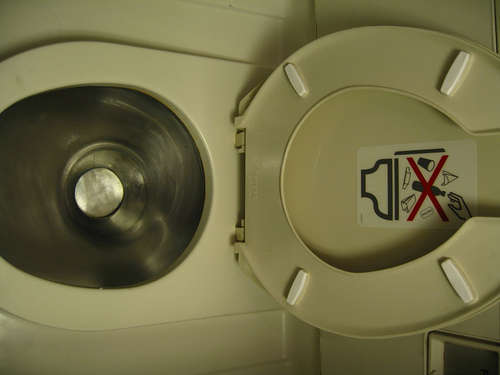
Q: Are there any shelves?
A: No, there are no shelves.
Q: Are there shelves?
A: No, there are no shelves.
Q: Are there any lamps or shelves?
A: No, there are no shelves or lamps.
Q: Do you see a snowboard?
A: No, there are no snowboards.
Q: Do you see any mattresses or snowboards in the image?
A: No, there are no snowboards or mattresses.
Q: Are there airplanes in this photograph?
A: Yes, there is an airplane.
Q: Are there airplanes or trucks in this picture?
A: Yes, there is an airplane.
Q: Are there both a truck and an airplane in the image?
A: No, there is an airplane but no trucks.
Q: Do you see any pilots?
A: No, there are no pilots.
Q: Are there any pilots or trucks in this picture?
A: No, there are no pilots or trucks.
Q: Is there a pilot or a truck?
A: No, there are no pilots or trucks.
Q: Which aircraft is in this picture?
A: The aircraft is an airplane.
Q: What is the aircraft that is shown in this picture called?
A: The aircraft is an airplane.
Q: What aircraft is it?
A: The aircraft is an airplane.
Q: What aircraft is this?
A: This is an airplane.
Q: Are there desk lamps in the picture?
A: No, there are no desk lamps.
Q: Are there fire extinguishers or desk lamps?
A: No, there are no desk lamps or fire extinguishers.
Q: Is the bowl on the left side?
A: Yes, the bowl is on the left of the image.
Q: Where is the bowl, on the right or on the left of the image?
A: The bowl is on the left of the image.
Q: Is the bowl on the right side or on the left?
A: The bowl is on the left of the image.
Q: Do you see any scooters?
A: No, there are no scooters.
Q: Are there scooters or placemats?
A: No, there are no scooters or placemats.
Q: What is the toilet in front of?
A: The toilet is in front of the wall.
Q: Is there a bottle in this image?
A: Yes, there is a bottle.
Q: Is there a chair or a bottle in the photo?
A: Yes, there is a bottle.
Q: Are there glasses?
A: No, there are no glasses.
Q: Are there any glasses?
A: No, there are no glasses.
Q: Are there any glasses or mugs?
A: No, there are no glasses or mugs.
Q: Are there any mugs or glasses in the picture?
A: No, there are no glasses or mugs.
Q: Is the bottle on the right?
A: Yes, the bottle is on the right of the image.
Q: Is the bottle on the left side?
A: No, the bottle is on the right of the image.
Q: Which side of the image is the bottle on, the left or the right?
A: The bottle is on the right of the image.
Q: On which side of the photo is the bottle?
A: The bottle is on the right of the image.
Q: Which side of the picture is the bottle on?
A: The bottle is on the right of the image.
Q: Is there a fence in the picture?
A: No, there are no fences.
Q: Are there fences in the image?
A: No, there are no fences.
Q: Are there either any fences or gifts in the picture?
A: No, there are no fences or gifts.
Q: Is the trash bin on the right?
A: Yes, the trash bin is on the right of the image.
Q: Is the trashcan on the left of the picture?
A: No, the trashcan is on the right of the image.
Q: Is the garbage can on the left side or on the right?
A: The garbage can is on the right of the image.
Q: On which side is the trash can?
A: The trash can is on the right of the image.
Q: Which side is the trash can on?
A: The trash can is on the right of the image.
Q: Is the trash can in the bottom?
A: Yes, the trash can is in the bottom of the image.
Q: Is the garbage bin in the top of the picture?
A: No, the garbage bin is in the bottom of the image.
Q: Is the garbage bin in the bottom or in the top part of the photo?
A: The garbage bin is in the bottom of the image.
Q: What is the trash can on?
A: The trash can is on the wall.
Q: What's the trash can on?
A: The trash can is on the wall.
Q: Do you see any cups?
A: Yes, there is a cup.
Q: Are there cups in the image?
A: Yes, there is a cup.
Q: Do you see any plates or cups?
A: Yes, there is a cup.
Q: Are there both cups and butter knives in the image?
A: No, there is a cup but no butter knives.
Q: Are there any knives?
A: No, there are no knives.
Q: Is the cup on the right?
A: Yes, the cup is on the right of the image.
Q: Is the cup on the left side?
A: No, the cup is on the right of the image.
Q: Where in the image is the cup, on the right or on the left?
A: The cup is on the right of the image.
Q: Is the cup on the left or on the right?
A: The cup is on the right of the image.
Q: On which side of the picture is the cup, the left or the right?
A: The cup is on the right of the image.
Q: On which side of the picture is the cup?
A: The cup is on the right of the image.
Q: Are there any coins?
A: No, there are no coins.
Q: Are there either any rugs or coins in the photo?
A: No, there are no coins or rugs.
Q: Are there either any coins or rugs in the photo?
A: No, there are no coins or rugs.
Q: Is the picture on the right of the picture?
A: Yes, the picture is on the right of the image.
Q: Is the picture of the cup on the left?
A: No, the picture is on the right of the image.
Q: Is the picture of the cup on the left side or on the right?
A: The picture is on the right of the image.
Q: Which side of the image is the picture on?
A: The picture is on the right of the image.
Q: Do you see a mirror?
A: No, there are no mirrors.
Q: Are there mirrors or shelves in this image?
A: No, there are no mirrors or shelves.